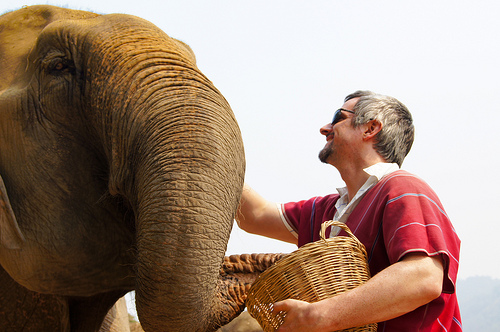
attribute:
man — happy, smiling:
[235, 89, 464, 331]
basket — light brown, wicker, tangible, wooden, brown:
[244, 219, 379, 331]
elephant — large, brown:
[0, 3, 290, 330]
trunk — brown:
[101, 28, 290, 330]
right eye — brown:
[53, 60, 71, 72]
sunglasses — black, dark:
[331, 108, 373, 124]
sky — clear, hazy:
[0, 0, 500, 279]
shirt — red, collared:
[275, 162, 463, 331]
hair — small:
[61, 2, 69, 8]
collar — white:
[333, 162, 400, 217]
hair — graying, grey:
[343, 89, 415, 169]